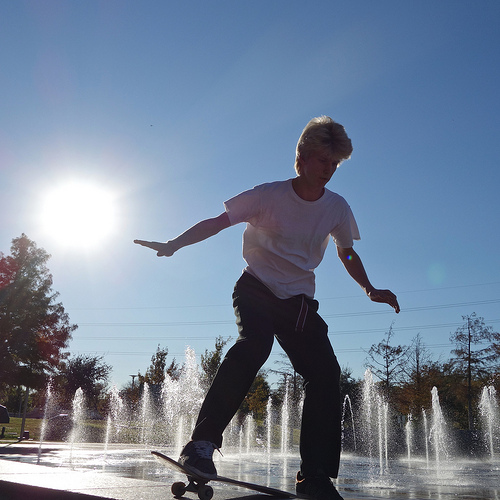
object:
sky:
[2, 0, 490, 396]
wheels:
[172, 481, 189, 498]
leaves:
[0, 339, 32, 385]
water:
[20, 353, 497, 488]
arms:
[167, 180, 287, 255]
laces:
[192, 440, 212, 458]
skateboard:
[148, 446, 301, 498]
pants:
[183, 267, 345, 486]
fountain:
[26, 338, 499, 500]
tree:
[0, 232, 77, 420]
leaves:
[37, 278, 51, 298]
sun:
[33, 171, 123, 252]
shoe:
[174, 438, 218, 481]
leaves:
[40, 322, 66, 362]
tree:
[50, 349, 111, 422]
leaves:
[58, 363, 94, 389]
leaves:
[86, 374, 109, 403]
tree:
[194, 336, 234, 382]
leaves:
[199, 339, 224, 373]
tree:
[264, 351, 307, 423]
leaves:
[270, 371, 294, 392]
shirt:
[224, 180, 363, 300]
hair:
[299, 121, 345, 151]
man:
[135, 115, 401, 499]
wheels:
[198, 484, 214, 500]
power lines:
[74, 310, 230, 334]